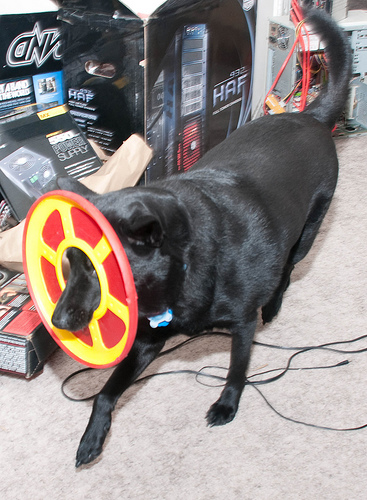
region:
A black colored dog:
[23, 3, 355, 468]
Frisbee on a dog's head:
[17, 186, 200, 372]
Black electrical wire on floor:
[60, 326, 364, 436]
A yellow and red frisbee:
[21, 185, 141, 372]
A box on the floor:
[2, 262, 62, 384]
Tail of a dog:
[300, 4, 356, 127]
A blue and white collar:
[140, 304, 185, 338]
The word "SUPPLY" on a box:
[53, 139, 92, 165]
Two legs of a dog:
[72, 321, 257, 473]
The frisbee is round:
[18, 186, 145, 375]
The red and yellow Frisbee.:
[17, 195, 134, 364]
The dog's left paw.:
[65, 425, 111, 462]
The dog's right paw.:
[205, 399, 234, 425]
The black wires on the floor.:
[49, 321, 365, 429]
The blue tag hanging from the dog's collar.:
[147, 306, 175, 325]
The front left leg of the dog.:
[83, 332, 144, 437]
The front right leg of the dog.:
[218, 314, 257, 399]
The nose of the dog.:
[50, 309, 78, 326]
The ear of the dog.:
[127, 216, 162, 246]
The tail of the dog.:
[300, 11, 349, 124]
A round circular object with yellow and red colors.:
[19, 186, 139, 372]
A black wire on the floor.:
[58, 327, 364, 438]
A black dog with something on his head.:
[21, 2, 363, 465]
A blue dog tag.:
[147, 307, 176, 334]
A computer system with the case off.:
[266, 16, 365, 136]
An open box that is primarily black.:
[54, 0, 257, 185]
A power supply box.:
[0, 104, 114, 221]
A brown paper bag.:
[78, 133, 155, 192]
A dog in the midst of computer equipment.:
[0, 0, 365, 467]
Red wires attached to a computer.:
[262, 1, 318, 113]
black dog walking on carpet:
[31, 24, 348, 468]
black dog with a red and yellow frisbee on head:
[19, 151, 269, 472]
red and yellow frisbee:
[18, 176, 144, 379]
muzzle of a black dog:
[40, 263, 96, 342]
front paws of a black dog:
[72, 377, 254, 481]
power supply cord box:
[5, 118, 102, 200]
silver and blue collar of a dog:
[138, 284, 189, 344]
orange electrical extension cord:
[267, 1, 314, 117]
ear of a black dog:
[123, 200, 191, 255]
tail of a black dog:
[294, 7, 354, 140]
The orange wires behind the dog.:
[282, 6, 319, 115]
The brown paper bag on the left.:
[0, 115, 151, 262]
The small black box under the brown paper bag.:
[3, 266, 51, 372]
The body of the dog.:
[174, 115, 332, 313]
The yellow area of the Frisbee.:
[36, 208, 125, 361]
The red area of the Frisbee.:
[23, 196, 135, 363]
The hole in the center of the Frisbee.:
[50, 241, 109, 318]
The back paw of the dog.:
[262, 255, 286, 326]